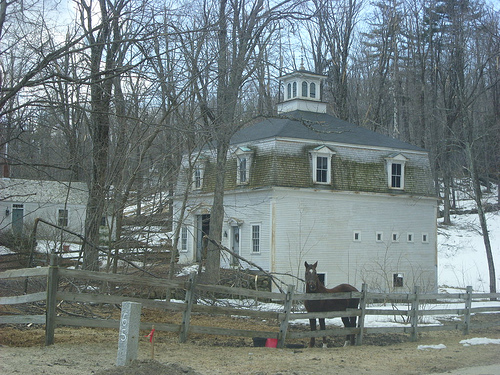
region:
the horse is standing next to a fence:
[290, 252, 372, 350]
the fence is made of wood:
[6, 255, 498, 342]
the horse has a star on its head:
[300, 257, 323, 294]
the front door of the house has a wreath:
[220, 212, 249, 274]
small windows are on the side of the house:
[344, 225, 434, 250]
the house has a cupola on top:
[278, 42, 331, 142]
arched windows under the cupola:
[282, 72, 322, 99]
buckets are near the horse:
[248, 328, 285, 352]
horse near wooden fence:
[289, 258, 371, 361]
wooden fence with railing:
[0, 253, 498, 351]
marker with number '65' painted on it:
[107, 293, 144, 374]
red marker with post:
[142, 320, 171, 366]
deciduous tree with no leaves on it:
[170, 7, 267, 299]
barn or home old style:
[160, 46, 460, 317]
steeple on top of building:
[267, 48, 339, 127]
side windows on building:
[292, 139, 345, 201]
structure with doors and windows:
[5, 170, 132, 246]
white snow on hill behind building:
[445, 228, 487, 285]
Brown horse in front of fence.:
[301, 261, 364, 348]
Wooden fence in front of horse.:
[2, 252, 499, 345]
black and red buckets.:
[248, 333, 279, 348]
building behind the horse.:
[162, 57, 442, 298]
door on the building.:
[224, 214, 246, 269]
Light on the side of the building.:
[3, 202, 12, 219]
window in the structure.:
[380, 148, 412, 197]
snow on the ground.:
[410, 333, 499, 354]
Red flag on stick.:
[145, 320, 159, 362]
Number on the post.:
[112, 304, 134, 346]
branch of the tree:
[73, 138, 151, 202]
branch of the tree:
[118, 31, 147, 56]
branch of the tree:
[391, 45, 445, 87]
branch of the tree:
[281, 3, 331, 31]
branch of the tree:
[240, 15, 267, 37]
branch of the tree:
[218, 5, 253, 39]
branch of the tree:
[182, 8, 220, 40]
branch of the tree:
[161, 18, 204, 54]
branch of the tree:
[130, 11, 171, 36]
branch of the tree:
[158, 25, 178, 49]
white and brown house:
[187, 103, 478, 345]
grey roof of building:
[238, 117, 398, 152]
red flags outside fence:
[135, 323, 282, 368]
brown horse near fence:
[315, 258, 362, 342]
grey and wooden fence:
[0, 277, 497, 325]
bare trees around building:
[12, 31, 227, 282]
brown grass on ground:
[190, 324, 435, 374]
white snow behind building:
[422, 208, 497, 268]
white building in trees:
[5, 183, 142, 244]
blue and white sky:
[28, 3, 175, 65]